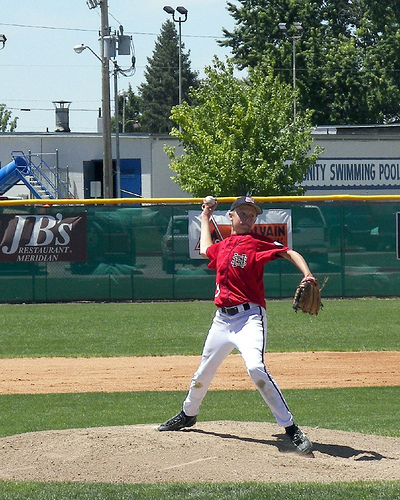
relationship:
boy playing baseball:
[156, 192, 324, 462] [198, 192, 222, 212]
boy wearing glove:
[156, 192, 324, 462] [293, 280, 323, 313]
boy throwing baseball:
[156, 192, 324, 462] [198, 192, 222, 212]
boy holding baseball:
[156, 192, 324, 462] [198, 192, 222, 212]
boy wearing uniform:
[156, 192, 324, 462] [205, 241, 295, 305]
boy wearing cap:
[156, 192, 324, 462] [227, 191, 266, 218]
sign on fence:
[0, 215, 86, 264] [0, 199, 396, 301]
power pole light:
[79, 0, 135, 197] [69, 42, 92, 61]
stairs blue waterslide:
[17, 171, 60, 199] [2, 147, 29, 200]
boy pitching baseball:
[156, 192, 324, 462] [198, 192, 222, 212]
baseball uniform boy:
[198, 192, 222, 212] [156, 192, 324, 462]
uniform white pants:
[181, 234, 295, 438] [177, 299, 297, 435]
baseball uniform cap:
[198, 192, 222, 212] [227, 191, 266, 218]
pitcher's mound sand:
[156, 192, 324, 462] [1, 422, 399, 476]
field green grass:
[1, 301, 399, 489] [0, 304, 399, 344]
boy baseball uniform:
[156, 192, 324, 462] [181, 234, 295, 438]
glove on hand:
[293, 280, 323, 313] [288, 276, 331, 319]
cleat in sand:
[280, 424, 320, 458] [1, 422, 399, 476]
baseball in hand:
[198, 192, 222, 212] [196, 194, 223, 215]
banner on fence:
[0, 215, 86, 264] [0, 199, 396, 301]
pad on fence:
[1, 195, 399, 205] [0, 199, 396, 301]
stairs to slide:
[17, 171, 60, 199] [2, 147, 29, 200]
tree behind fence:
[161, 64, 324, 195] [0, 199, 396, 301]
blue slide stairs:
[1, 154, 59, 200] [17, 171, 60, 199]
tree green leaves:
[161, 64, 324, 195] [161, 64, 324, 195]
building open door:
[3, 125, 399, 198] [82, 157, 142, 198]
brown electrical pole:
[92, 2, 122, 196] [79, 0, 135, 197]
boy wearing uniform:
[156, 192, 324, 462] [181, 234, 295, 438]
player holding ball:
[156, 192, 324, 462] [198, 192, 222, 212]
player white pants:
[156, 192, 324, 462] [177, 299, 297, 435]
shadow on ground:
[179, 421, 399, 468] [1, 301, 399, 489]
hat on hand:
[227, 191, 266, 218] [288, 276, 331, 319]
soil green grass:
[2, 358, 400, 387] [0, 304, 399, 344]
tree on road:
[161, 64, 324, 195] [140, 249, 399, 274]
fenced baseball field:
[0, 199, 396, 301] [1, 301, 399, 489]